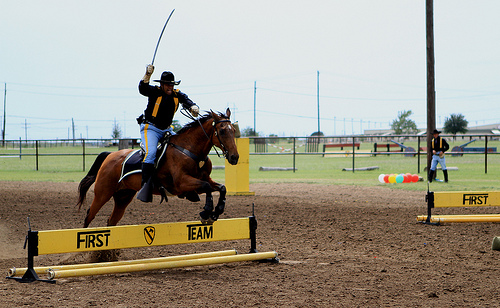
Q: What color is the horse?
A: Brown.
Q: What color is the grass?
A: Green.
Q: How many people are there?
A: Two.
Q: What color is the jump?
A: Yellow.